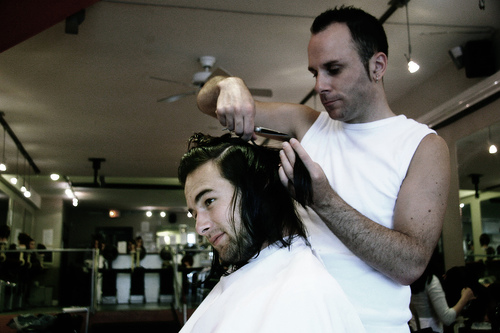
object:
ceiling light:
[401, 58, 423, 74]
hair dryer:
[82, 250, 103, 305]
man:
[160, 125, 367, 333]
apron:
[172, 232, 376, 332]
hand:
[214, 75, 260, 142]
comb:
[256, 124, 291, 138]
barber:
[195, 0, 461, 333]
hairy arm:
[332, 137, 459, 288]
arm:
[425, 273, 463, 328]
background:
[1, 155, 499, 323]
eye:
[202, 197, 219, 205]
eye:
[192, 212, 199, 218]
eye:
[310, 71, 320, 78]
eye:
[327, 65, 342, 75]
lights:
[49, 172, 63, 181]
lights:
[8, 176, 23, 186]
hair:
[171, 126, 315, 250]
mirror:
[478, 193, 499, 260]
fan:
[148, 52, 274, 106]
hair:
[309, 3, 394, 82]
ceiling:
[15, 62, 178, 192]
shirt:
[285, 108, 442, 331]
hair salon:
[0, 0, 500, 331]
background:
[15, 42, 293, 83]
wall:
[454, 106, 498, 257]